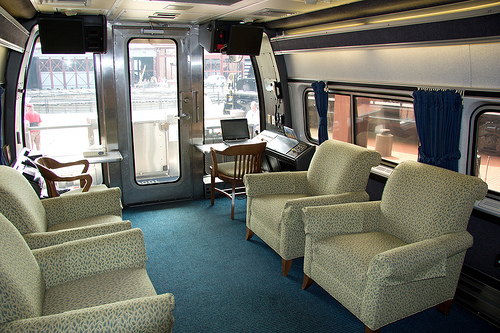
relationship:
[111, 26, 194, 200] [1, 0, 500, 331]
door is silver door in room room has chair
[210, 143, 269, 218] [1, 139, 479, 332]
chair is wooden chair in room room has chair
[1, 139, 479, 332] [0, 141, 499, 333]
chair is white chair blue chair has pattern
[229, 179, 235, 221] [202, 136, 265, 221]
leg is wooden chair has leg chair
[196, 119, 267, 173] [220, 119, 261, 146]
desk has laptop laptop on desk laptop is open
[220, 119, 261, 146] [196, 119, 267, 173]
laptop is open laptop on desk desk has laptop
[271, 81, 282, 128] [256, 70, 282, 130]
telephone is on wall telephone above wall has telephone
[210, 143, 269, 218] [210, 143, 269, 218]
chair is brown chair barrel chair is wooden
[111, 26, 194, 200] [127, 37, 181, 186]
door has window windows full length window is on door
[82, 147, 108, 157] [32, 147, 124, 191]
box is on desk chair barrel desk is by chair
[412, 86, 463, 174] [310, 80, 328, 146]
curtain is blue curtain house curtain is blue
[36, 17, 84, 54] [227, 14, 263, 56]
monitor is little monitors flatscreen flatscreen is little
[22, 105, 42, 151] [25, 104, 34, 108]
man is wearing shirt shirt red hat is red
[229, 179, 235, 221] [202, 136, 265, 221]
leg is brown chair has leg chair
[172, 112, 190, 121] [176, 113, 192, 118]
door has handle handle on door door is handled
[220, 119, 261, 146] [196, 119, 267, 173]
computer is laptop laptop on desk desk has computer